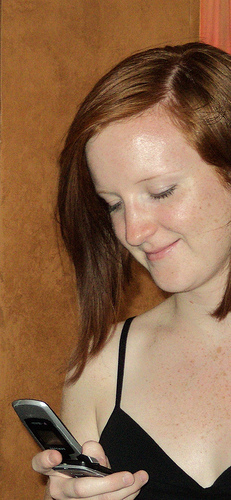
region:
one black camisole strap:
[111, 314, 133, 408]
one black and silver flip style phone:
[10, 398, 118, 477]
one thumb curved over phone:
[81, 440, 110, 473]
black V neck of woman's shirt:
[151, 436, 230, 497]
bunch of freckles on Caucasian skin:
[158, 339, 227, 433]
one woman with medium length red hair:
[50, 38, 230, 351]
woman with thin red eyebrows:
[89, 171, 188, 215]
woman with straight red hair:
[47, 38, 224, 376]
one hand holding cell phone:
[7, 394, 148, 499]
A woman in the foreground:
[2, 36, 228, 498]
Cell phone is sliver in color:
[6, 393, 138, 499]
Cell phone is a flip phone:
[6, 392, 128, 499]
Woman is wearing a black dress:
[79, 307, 227, 497]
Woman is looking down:
[66, 110, 228, 309]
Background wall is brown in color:
[1, 0, 197, 496]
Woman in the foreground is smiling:
[66, 108, 230, 311]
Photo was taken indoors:
[1, 2, 228, 499]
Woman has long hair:
[31, 36, 229, 387]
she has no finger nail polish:
[121, 473, 132, 485]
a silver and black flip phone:
[12, 399, 115, 475]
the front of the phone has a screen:
[31, 425, 60, 447]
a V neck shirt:
[117, 403, 229, 486]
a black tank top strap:
[113, 316, 136, 408]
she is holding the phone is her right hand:
[13, 394, 149, 499]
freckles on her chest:
[160, 341, 229, 448]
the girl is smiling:
[142, 234, 184, 264]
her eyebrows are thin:
[134, 171, 175, 185]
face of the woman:
[87, 141, 217, 294]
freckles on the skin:
[166, 365, 220, 440]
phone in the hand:
[9, 401, 129, 494]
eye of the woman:
[143, 174, 180, 200]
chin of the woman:
[152, 275, 189, 294]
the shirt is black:
[157, 475, 190, 488]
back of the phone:
[57, 459, 99, 473]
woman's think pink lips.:
[144, 243, 181, 260]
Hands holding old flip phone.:
[11, 398, 109, 478]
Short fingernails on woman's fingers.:
[121, 470, 136, 487]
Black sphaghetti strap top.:
[117, 319, 138, 408]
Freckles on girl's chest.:
[168, 366, 226, 397]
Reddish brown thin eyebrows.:
[135, 170, 183, 185]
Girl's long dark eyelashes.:
[149, 186, 177, 199]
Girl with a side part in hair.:
[146, 56, 186, 106]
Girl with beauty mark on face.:
[196, 203, 211, 215]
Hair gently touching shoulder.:
[67, 324, 114, 383]